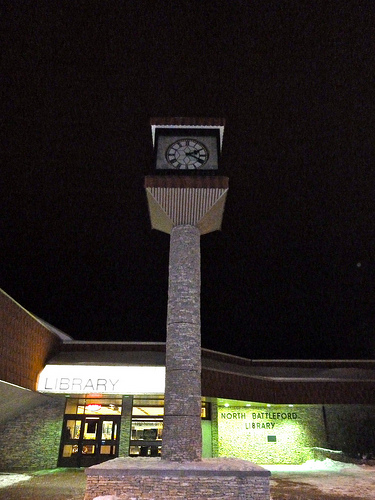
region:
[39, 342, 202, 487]
the library is open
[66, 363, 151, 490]
the library is open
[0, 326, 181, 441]
the library is open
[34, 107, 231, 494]
tall clock tower in front of a library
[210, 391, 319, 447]
North Battleford Library sign on the front of a building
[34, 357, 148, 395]
lit library sign on the front of a building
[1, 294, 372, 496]
brown stone library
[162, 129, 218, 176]
clock face on the front of a clock tower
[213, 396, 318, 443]
four lights lighting a library sign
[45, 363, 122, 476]
entrance doors of a library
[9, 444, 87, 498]
walkway leading to a library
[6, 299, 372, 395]
roof line of a library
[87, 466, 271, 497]
tan bricks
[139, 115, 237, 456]
clock tower at the library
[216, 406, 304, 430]
name of the library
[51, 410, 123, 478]
main entrance of the library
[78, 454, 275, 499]
base of the clock tower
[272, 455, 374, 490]
snow pile from cleared sidewalk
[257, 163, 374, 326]
evening sky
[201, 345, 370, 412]
portico of the front entrance of the library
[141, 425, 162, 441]
display in the window of the library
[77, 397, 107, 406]
exit sign at the main entrance of the library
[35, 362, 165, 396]
sign above the main entrance of the library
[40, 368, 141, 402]
The lighted sign reads library?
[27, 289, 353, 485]
The building is a library.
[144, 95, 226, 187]
A clock on the pole.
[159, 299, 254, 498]
The pole is made of brick.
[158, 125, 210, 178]
The clock has roman numbers.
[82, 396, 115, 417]
The light in the library is turned on.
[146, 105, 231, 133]
The top of the clock is brown.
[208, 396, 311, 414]
The building has skylights on.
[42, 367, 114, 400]
The sign is lighted up.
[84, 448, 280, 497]
the base of the bole is made of bricks.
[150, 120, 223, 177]
Clock at the top of the tower.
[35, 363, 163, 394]
Very bright lit-up sign.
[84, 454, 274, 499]
Brick base at the bottom of the tower.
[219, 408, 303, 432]
Name of the library on the building.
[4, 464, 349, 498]
Shadow of the building.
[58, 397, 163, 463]
Door to the library.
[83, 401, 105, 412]
Light inside the library.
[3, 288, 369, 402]
Rooftop of the library.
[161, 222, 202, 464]
Round brick tower that is tall.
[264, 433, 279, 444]
Plate on the building.